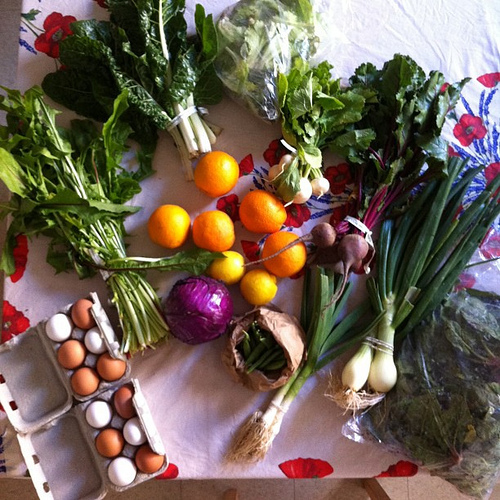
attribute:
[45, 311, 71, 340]
egg — white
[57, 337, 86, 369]
egg — brown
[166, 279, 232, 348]
cabbage — purple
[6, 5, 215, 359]
leafy greens — bundled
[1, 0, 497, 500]
vegetables — green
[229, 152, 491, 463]
stalks — cut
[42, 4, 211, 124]
leaves — green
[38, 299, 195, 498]
eggs — brown, white, dozen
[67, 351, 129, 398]
eggs — brown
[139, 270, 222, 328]
onion — purple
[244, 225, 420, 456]
onions — spring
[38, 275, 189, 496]
eggs — half dozen, white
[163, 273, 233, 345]
onion — red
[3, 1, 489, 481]
tablecloth — white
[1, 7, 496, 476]
flower — red, designs, tablecloth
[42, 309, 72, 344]
egg — white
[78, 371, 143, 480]
eggs — white, brown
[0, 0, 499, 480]
table cloth — white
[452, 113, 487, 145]
flower — red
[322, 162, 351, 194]
flower — red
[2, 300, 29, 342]
flower — red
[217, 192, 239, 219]
flower — red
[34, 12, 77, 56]
flower — red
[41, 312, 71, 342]
egg — brown, white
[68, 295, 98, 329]
egg — brown, white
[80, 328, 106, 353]
egg — brown, white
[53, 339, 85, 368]
egg — brown, white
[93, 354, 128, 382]
egg — brown, white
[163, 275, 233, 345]
cabbage — red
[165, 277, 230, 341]
onion — purple